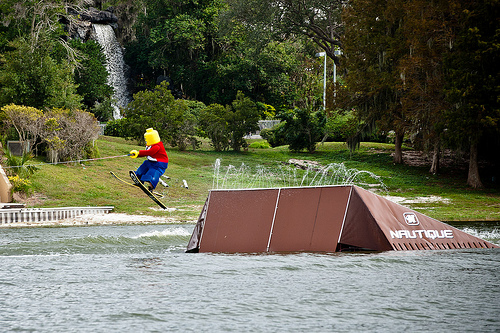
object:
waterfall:
[95, 24, 128, 121]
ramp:
[186, 185, 500, 253]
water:
[0, 225, 500, 332]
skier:
[128, 128, 171, 193]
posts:
[323, 50, 326, 110]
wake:
[0, 231, 204, 257]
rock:
[77, 8, 119, 25]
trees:
[0, 0, 498, 188]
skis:
[129, 170, 168, 209]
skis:
[110, 170, 168, 210]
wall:
[0, 206, 114, 224]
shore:
[0, 135, 499, 224]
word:
[390, 230, 455, 240]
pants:
[134, 160, 168, 190]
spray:
[211, 158, 390, 198]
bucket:
[144, 128, 161, 146]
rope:
[0, 154, 129, 169]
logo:
[403, 212, 420, 226]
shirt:
[139, 141, 169, 163]